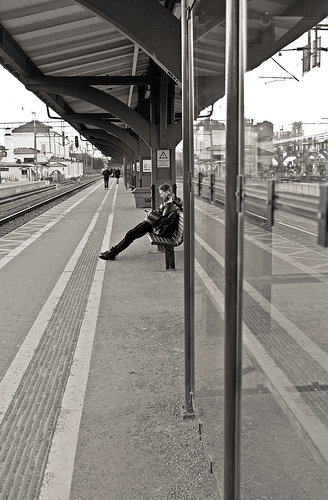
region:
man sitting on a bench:
[74, 173, 232, 280]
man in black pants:
[86, 172, 226, 293]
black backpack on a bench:
[153, 208, 186, 267]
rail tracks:
[1, 153, 100, 248]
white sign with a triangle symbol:
[152, 144, 174, 173]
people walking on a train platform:
[66, 163, 127, 204]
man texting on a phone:
[75, 173, 187, 270]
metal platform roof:
[7, 1, 325, 157]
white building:
[3, 117, 91, 189]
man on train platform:
[99, 182, 188, 269]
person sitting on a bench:
[104, 175, 201, 269]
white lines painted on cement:
[67, 203, 127, 436]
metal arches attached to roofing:
[14, 56, 187, 139]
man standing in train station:
[97, 161, 120, 194]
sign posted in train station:
[155, 142, 172, 172]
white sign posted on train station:
[139, 154, 155, 178]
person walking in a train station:
[112, 162, 126, 191]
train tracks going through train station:
[0, 180, 100, 237]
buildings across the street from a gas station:
[15, 109, 77, 194]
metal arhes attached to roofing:
[55, 107, 134, 180]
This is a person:
[94, 182, 186, 277]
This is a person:
[101, 166, 110, 192]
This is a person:
[113, 164, 121, 186]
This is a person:
[109, 164, 116, 184]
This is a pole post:
[214, 0, 256, 497]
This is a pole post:
[175, 7, 199, 433]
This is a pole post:
[149, 151, 162, 253]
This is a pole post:
[136, 162, 144, 213]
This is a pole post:
[166, 147, 183, 237]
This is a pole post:
[134, 155, 148, 208]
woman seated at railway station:
[99, 180, 181, 281]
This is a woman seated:
[92, 183, 181, 268]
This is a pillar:
[174, 4, 208, 444]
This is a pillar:
[218, 16, 254, 493]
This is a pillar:
[164, 80, 182, 269]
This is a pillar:
[140, 85, 163, 245]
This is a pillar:
[135, 146, 146, 206]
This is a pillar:
[132, 155, 137, 198]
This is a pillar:
[120, 157, 130, 191]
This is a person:
[98, 161, 114, 192]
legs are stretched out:
[94, 215, 159, 265]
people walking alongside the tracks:
[75, 162, 123, 188]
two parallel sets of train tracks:
[0, 165, 108, 233]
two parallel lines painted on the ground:
[2, 196, 119, 499]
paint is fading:
[108, 200, 117, 214]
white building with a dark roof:
[4, 120, 88, 179]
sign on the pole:
[155, 150, 171, 170]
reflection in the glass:
[194, 121, 277, 176]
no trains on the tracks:
[0, 161, 101, 243]